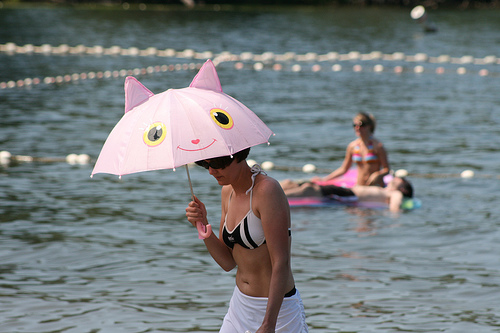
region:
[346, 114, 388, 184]
a girl in bikini out of focus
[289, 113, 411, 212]
a mom playing with her son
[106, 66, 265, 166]
a hello kitty like umbrella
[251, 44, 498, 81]
various protection buoys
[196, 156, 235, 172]
dark sunglasses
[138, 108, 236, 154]
a smiley figure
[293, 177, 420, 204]
a boy floating on the beach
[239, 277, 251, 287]
the sexy woman's belly button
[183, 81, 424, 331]
three people on the beach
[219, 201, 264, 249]
brazier black and white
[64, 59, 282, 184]
kitty face on a pink umbrella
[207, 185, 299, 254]
black and white bathing suit top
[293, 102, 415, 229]
people sitting on floats in the water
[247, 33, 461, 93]
buoys in the water to rope it off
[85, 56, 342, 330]
woman walking with a pink umbrella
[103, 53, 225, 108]
cat ears on top of the umbrella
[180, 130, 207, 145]
pink heart shape for cat nose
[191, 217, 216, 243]
pink handle of umbrella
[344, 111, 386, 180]
woman wearing sunglasses while in the water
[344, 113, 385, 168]
woman wearing a striped bathing suit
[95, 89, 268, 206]
woman is holding pink umbrella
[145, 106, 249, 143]
yellow and black eyes on umbrella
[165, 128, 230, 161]
pink nose and mouth on umbrella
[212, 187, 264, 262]
woman wears black and white bikini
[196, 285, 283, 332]
woman is wearing white shorts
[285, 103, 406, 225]
two people relaxing in water behind woman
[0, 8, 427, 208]
white buoys in water behind woman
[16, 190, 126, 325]
water behind woman is blue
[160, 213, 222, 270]
woman holds umbrella at pink handle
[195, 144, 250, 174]
woman holding umbrella has dark hair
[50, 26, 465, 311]
woman carrying pink umbrella by water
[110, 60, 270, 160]
face of smiling cat with pointy ears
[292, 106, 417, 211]
woman standing by floating person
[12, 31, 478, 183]
pink and white floating dividers on water surface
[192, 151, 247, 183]
woman in sunglasses looking down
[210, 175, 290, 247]
black and white bikini top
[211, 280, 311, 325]
white fabric wrapped below waist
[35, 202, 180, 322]
swirling design on water surface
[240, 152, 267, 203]
white strings tied together at neck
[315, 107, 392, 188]
person in water hip deep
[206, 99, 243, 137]
right eye on umbrella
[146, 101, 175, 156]
left eye on umbrella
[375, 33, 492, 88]
white floatation items in water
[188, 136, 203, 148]
pink cat heart nose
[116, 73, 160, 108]
pink ear on left of photo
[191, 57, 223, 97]
pink ear on right of photo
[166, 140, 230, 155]
pink smile on cat umbrella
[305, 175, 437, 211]
man floating on raft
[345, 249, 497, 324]
water on lower portion of picture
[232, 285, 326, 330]
white swimsuit coverup